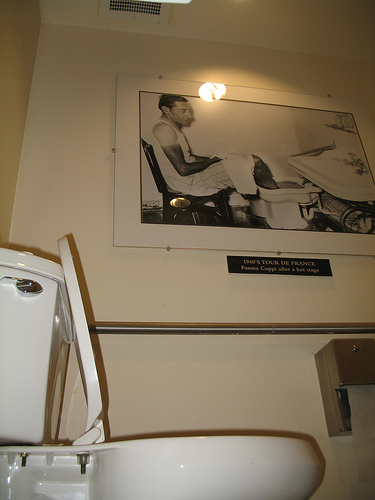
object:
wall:
[0, 0, 24, 132]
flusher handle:
[0, 272, 44, 298]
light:
[196, 80, 230, 104]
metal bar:
[89, 320, 375, 336]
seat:
[97, 422, 326, 497]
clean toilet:
[0, 234, 325, 498]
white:
[0, 314, 37, 401]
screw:
[166, 245, 172, 251]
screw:
[276, 250, 282, 255]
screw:
[110, 146, 115, 152]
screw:
[159, 75, 163, 79]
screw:
[325, 93, 333, 98]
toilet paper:
[336, 382, 375, 482]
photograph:
[133, 90, 375, 235]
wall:
[137, 277, 370, 316]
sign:
[223, 254, 335, 277]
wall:
[45, 34, 107, 158]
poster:
[226, 255, 332, 278]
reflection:
[195, 80, 238, 107]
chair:
[139, 135, 233, 230]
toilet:
[0, 234, 328, 500]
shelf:
[311, 332, 374, 440]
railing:
[302, 318, 370, 341]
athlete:
[149, 95, 276, 198]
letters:
[280, 260, 285, 266]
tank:
[0, 243, 75, 446]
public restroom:
[0, 0, 375, 500]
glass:
[114, 72, 375, 256]